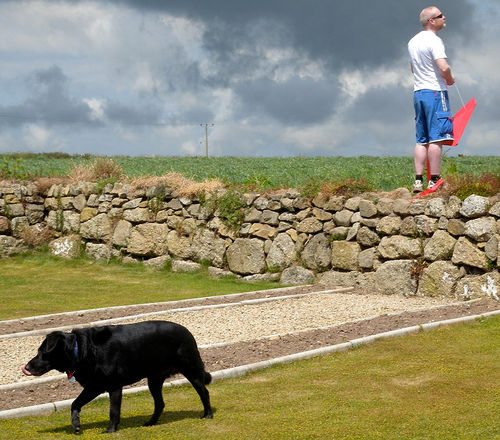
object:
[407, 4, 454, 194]
man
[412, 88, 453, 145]
shorts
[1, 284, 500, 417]
walkway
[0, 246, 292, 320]
grass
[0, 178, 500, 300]
wall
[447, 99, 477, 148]
kite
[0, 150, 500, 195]
field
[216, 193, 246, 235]
plant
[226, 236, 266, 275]
stone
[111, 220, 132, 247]
stone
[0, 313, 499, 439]
grass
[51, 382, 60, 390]
stone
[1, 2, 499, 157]
sky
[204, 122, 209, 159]
telephone pole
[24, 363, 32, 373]
nose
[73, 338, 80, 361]
collar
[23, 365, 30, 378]
tongue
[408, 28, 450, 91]
shirt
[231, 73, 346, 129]
cloud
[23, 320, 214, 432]
dog